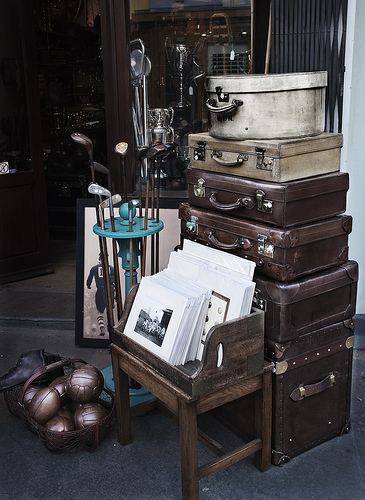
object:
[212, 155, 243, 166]
buckle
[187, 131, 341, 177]
trunk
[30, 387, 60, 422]
balls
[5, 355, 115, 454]
basket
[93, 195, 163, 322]
holder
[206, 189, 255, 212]
handle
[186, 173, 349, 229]
suitcase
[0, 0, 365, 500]
golf club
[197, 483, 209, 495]
spot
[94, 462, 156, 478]
carpet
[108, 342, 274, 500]
bench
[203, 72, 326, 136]
luggage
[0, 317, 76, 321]
step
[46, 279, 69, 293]
floor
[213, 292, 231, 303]
frame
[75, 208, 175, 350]
picture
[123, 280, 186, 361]
pictures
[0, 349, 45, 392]
shoes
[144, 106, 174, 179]
trophy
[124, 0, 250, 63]
window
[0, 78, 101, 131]
gate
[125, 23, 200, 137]
merchandise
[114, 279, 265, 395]
crate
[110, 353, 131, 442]
stand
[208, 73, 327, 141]
box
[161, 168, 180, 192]
case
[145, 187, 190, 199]
table